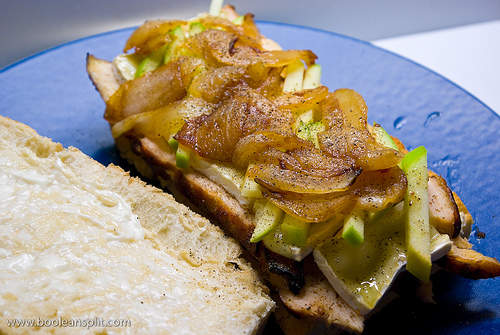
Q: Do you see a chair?
A: No, there are no chairs.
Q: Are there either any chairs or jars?
A: No, there are no chairs or jars.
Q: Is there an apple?
A: Yes, there is an apple.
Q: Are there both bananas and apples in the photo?
A: No, there is an apple but no bananas.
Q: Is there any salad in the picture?
A: No, there is no salad.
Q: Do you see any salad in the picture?
A: No, there is no salad.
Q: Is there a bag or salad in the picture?
A: No, there are no salad or bags.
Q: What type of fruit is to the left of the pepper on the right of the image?
A: The fruit is an apple.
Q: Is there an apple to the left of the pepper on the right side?
A: Yes, there is an apple to the left of the pepper.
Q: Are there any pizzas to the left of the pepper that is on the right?
A: No, there is an apple to the left of the pepper.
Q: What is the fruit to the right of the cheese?
A: The fruit is an apple.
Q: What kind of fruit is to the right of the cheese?
A: The fruit is an apple.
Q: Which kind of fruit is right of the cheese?
A: The fruit is an apple.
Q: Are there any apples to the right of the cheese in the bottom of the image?
A: Yes, there is an apple to the right of the cheese.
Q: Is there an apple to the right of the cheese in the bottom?
A: Yes, there is an apple to the right of the cheese.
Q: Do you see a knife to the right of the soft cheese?
A: No, there is an apple to the right of the cheese.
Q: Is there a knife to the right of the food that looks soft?
A: No, there is an apple to the right of the cheese.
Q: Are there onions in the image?
A: Yes, there are onions.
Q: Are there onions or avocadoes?
A: Yes, there are onions.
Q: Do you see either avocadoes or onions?
A: Yes, there are onions.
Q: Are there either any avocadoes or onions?
A: Yes, there are onions.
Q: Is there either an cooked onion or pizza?
A: Yes, there are cooked onions.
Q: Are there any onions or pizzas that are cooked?
A: Yes, the onions are cooked.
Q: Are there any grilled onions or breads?
A: Yes, there are grilled onions.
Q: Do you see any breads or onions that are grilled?
A: Yes, the onions are grilled.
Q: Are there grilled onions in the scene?
A: Yes, there are grilled onions.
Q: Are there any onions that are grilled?
A: Yes, there are onions that are grilled.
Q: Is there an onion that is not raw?
A: Yes, there are grilled onions.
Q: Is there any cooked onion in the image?
A: Yes, there are cooked onions.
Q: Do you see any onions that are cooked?
A: Yes, there are onions that are cooked.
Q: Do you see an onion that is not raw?
A: Yes, there are cooked onions.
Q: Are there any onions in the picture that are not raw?
A: Yes, there are cooked onions.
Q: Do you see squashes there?
A: No, there are no squashes.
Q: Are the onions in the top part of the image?
A: Yes, the onions are in the top of the image.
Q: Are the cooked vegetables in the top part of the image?
A: Yes, the onions are in the top of the image.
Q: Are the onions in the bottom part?
A: No, the onions are in the top of the image.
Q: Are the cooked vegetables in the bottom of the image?
A: No, the onions are in the top of the image.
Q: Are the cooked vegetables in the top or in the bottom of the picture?
A: The onions are in the top of the image.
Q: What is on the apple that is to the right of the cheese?
A: The onions are on the apple.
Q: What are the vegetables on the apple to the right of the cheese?
A: The vegetables are onions.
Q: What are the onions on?
A: The onions are on the apple.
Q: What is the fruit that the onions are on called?
A: The fruit is an apple.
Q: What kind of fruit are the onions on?
A: The onions are on the apple.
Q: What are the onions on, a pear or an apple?
A: The onions are on an apple.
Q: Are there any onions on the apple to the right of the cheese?
A: Yes, there are onions on the apple.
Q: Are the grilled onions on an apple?
A: Yes, the onions are on an apple.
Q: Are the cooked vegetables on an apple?
A: Yes, the onions are on an apple.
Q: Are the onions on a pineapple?
A: No, the onions are on an apple.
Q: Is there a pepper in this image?
A: Yes, there is a pepper.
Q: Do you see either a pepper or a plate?
A: Yes, there is a pepper.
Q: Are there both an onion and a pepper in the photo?
A: Yes, there are both a pepper and an onion.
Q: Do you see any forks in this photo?
A: No, there are no forks.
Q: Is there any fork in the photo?
A: No, there are no forks.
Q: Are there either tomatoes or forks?
A: No, there are no forks or tomatoes.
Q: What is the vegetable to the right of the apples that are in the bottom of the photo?
A: The vegetable is a pepper.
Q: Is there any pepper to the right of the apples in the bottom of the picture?
A: Yes, there is a pepper to the right of the apples.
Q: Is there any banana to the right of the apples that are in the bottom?
A: No, there is a pepper to the right of the apples.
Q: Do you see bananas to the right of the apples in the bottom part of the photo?
A: No, there is a pepper to the right of the apples.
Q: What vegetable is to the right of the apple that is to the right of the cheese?
A: The vegetable is a pepper.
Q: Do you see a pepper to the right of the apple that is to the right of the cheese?
A: Yes, there is a pepper to the right of the apple.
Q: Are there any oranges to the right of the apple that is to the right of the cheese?
A: No, there is a pepper to the right of the apple.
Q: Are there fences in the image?
A: No, there are no fences.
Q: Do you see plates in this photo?
A: Yes, there is a plate.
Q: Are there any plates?
A: Yes, there is a plate.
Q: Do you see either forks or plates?
A: Yes, there is a plate.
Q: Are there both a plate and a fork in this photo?
A: No, there is a plate but no forks.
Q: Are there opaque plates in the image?
A: Yes, there is an opaque plate.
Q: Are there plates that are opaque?
A: Yes, there is a plate that is opaque.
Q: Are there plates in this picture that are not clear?
A: Yes, there is a opaque plate.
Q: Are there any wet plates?
A: Yes, there is a wet plate.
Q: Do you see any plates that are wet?
A: Yes, there is a plate that is wet.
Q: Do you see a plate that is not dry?
A: Yes, there is a wet plate.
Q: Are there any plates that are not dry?
A: Yes, there is a wet plate.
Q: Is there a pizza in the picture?
A: No, there are no pizzas.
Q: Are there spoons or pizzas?
A: No, there are no pizzas or spoons.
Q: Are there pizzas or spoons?
A: No, there are no pizzas or spoons.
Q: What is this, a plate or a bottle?
A: This is a plate.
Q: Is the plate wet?
A: Yes, the plate is wet.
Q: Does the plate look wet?
A: Yes, the plate is wet.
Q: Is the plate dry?
A: No, the plate is wet.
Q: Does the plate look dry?
A: No, the plate is wet.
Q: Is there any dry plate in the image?
A: No, there is a plate but it is wet.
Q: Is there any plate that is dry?
A: No, there is a plate but it is wet.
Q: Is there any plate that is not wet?
A: No, there is a plate but it is wet.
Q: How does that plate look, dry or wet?
A: The plate is wet.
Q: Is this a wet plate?
A: Yes, this is a wet plate.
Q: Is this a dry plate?
A: No, this is a wet plate.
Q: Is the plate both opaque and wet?
A: Yes, the plate is opaque and wet.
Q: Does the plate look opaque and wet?
A: Yes, the plate is opaque and wet.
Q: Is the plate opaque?
A: Yes, the plate is opaque.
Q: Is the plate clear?
A: No, the plate is opaque.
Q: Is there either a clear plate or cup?
A: No, there is a plate but it is opaque.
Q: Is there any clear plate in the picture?
A: No, there is a plate but it is opaque.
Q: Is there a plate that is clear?
A: No, there is a plate but it is opaque.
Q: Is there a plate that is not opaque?
A: No, there is a plate but it is opaque.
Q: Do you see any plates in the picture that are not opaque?
A: No, there is a plate but it is opaque.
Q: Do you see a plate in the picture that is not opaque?
A: No, there is a plate but it is opaque.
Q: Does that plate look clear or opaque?
A: The plate is opaque.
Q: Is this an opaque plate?
A: Yes, this is an opaque plate.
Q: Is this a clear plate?
A: No, this is an opaque plate.